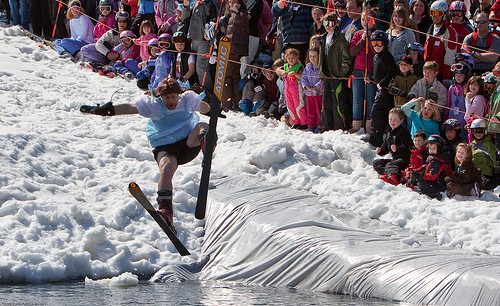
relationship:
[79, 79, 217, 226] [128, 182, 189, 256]
man wearing ski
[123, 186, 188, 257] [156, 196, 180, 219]
ski on bottom of foot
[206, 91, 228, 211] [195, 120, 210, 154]
ski on foot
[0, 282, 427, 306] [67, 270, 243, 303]
water of water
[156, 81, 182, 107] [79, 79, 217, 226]
head of man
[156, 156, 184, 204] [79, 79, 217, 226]
leg attached to man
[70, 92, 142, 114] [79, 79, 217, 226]
arm of man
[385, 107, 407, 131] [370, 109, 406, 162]
head on top of boy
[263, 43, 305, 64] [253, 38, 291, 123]
head on top of girl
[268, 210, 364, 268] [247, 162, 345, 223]
snow on top of ground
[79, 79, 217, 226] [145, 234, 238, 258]
man in air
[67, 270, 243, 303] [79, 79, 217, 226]
water below man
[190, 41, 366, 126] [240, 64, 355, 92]
children are in front of fence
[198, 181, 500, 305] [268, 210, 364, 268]
sheeting on top of snow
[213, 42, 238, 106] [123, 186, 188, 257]
atomic on bottom of ski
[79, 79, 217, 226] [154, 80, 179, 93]
man wearing wig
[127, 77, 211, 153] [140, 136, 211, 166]
man wearing shorts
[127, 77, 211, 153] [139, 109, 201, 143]
man wearing dress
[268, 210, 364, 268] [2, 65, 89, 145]
snow on top of slope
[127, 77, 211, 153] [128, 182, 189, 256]
man wearing ski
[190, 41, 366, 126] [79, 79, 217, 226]
children watching man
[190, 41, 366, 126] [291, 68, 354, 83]
children behind rope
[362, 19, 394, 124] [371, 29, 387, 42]
kid wearing helmet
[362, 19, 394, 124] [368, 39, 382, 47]
kid wearing goggles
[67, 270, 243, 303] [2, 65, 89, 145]
water at bottom of slope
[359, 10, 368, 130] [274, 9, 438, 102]
pole holding ropes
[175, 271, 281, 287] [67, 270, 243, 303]
sheeting into water